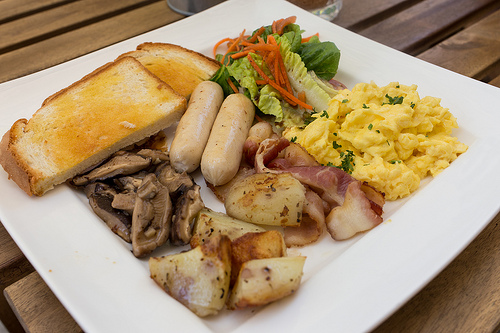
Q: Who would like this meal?
A: A hungry person.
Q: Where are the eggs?
A: Top right corner.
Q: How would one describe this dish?
A: A complete balanced meal served on a square white plate.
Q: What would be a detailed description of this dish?
A: A balanced meal of eggs, sausage links, tossed salad, roasted potatoes, bacon, sauteed mushrooms, and toast with butter.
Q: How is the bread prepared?
A: Toast cut in half on plate.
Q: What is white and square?
A: The plate, holding the food.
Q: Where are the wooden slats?
A: Below the plate.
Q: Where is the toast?
A: Beside the sausages, to the far left of the plate, as it faces the viewer.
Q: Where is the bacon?
A: To the left of the pile of yellow food, situated at the far right of the plate.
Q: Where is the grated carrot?
A: On a lettuce bed, located at the apex of the plate.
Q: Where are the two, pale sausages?
A: Near the middle of the plate, below the lettuce bed.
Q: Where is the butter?
A: Melted, on the two slices of toast.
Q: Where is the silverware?
A: There is none, visible.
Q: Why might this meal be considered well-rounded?
A: It has meat, starches and vegetables.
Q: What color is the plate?
A: White.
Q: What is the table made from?
A: Wood.